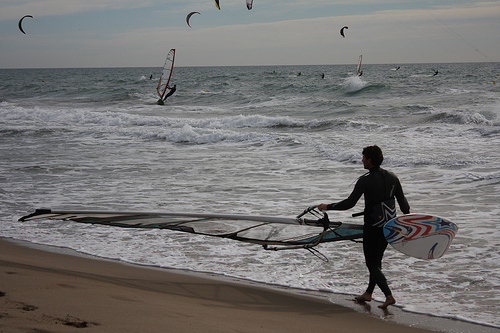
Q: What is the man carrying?
A: A wind surfboard.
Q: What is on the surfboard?
A: A sail.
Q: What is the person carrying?
A: Windsurfing board.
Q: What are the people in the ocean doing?
A: Windsurfing.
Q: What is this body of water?
A: Ocean.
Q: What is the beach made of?
A: Sand.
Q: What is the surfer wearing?
A: Black and white wetsuit.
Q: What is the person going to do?
A: Go windsurfing.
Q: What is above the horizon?
A: The sky.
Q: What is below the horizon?
A: The ocean.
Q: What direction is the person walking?
A: Left.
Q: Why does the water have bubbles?
A: Waves.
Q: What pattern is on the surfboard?
A: Blue and red stripes.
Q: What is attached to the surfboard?
A: A sail.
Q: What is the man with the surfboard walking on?
A: The sandy beach.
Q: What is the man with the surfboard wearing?
A: A black wetsuit.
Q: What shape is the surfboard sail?
A: Triangular.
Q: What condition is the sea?
A: Choppy.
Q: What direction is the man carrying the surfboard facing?
A: Toward the left.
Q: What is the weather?
A: Cloudy.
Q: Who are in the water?
A: Windsurfers.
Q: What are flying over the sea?
A: Seagulls.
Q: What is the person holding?
A: A sailboard.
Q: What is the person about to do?
A: Windsurf.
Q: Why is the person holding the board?
A: To surf.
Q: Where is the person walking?
A: On the sand.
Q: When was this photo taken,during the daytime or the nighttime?
A: Daytime.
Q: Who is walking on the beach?
A: A man.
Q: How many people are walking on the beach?
A: One.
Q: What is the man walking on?
A: Sand.